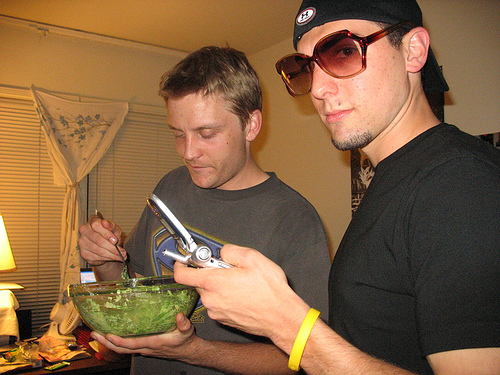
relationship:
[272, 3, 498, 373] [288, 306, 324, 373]
man wearing yellow bracelet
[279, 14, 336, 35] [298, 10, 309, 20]
logo with print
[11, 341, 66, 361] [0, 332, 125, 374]
clutter on room table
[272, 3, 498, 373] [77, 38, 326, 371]
man hanging out men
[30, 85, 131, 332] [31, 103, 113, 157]
curtain with flowers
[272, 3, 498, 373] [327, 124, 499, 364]
man in a black shirt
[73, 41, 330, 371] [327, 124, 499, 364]
man in a black shirt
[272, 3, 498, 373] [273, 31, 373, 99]
man wearing sunglasses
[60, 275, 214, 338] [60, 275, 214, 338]
bowl of bowl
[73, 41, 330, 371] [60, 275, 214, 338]
man with bowl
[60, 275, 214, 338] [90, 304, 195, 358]
bowl in hand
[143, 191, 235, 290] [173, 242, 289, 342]
phone in hand